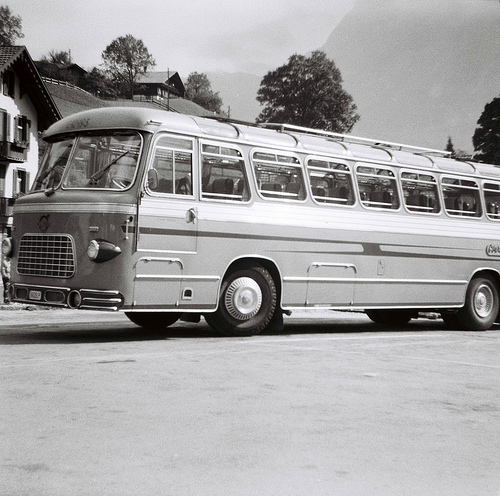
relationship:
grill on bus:
[17, 232, 77, 279] [2, 106, 499, 338]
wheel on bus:
[442, 274, 499, 330] [2, 106, 499, 338]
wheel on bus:
[204, 258, 279, 338] [2, 106, 499, 338]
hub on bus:
[224, 276, 263, 322] [2, 106, 499, 338]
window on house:
[1, 70, 15, 99] [1, 43, 65, 230]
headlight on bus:
[2, 238, 13, 258] [2, 106, 499, 338]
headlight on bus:
[85, 238, 99, 261] [2, 106, 499, 338]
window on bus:
[197, 138, 251, 203] [2, 106, 499, 338]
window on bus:
[250, 148, 308, 202] [2, 106, 499, 338]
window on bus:
[302, 155, 356, 209] [2, 106, 499, 338]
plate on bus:
[28, 289, 43, 303] [2, 106, 499, 338]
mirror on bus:
[146, 168, 159, 192] [2, 106, 499, 338]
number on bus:
[64, 117, 90, 130] [2, 106, 499, 338]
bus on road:
[2, 106, 499, 338] [3, 337, 499, 495]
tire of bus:
[204, 258, 279, 338] [2, 106, 499, 338]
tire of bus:
[442, 274, 499, 330] [2, 106, 499, 338]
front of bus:
[2, 108, 150, 308] [2, 106, 499, 338]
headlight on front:
[2, 238, 13, 258] [2, 108, 150, 308]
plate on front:
[28, 289, 43, 303] [2, 108, 150, 308]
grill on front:
[17, 232, 77, 279] [2, 108, 150, 308]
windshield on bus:
[31, 130, 144, 190] [2, 106, 499, 338]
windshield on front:
[31, 130, 144, 190] [2, 108, 150, 308]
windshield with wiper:
[31, 130, 144, 190] [89, 149, 132, 182]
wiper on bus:
[89, 149, 132, 182] [2, 106, 499, 338]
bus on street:
[2, 106, 499, 338] [3, 337, 499, 495]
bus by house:
[2, 106, 499, 338] [1, 43, 65, 230]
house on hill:
[100, 66, 186, 105] [47, 82, 171, 119]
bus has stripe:
[2, 106, 499, 338] [12, 191, 499, 242]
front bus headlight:
[2, 108, 150, 308] [2, 238, 13, 258]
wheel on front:
[442, 274, 499, 330] [2, 108, 150, 308]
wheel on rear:
[442, 274, 499, 330] [449, 156, 499, 310]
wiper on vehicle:
[89, 149, 132, 182] [2, 106, 499, 338]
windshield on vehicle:
[31, 130, 144, 190] [2, 106, 499, 338]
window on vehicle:
[197, 138, 251, 203] [2, 106, 499, 338]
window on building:
[1, 70, 15, 99] [1, 43, 65, 230]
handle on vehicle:
[186, 207, 197, 223] [2, 106, 499, 338]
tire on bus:
[125, 310, 182, 330] [2, 106, 499, 338]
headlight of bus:
[2, 238, 13, 258] [2, 106, 499, 338]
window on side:
[302, 155, 356, 209] [2, 106, 499, 338]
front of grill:
[2, 108, 150, 308] [17, 232, 77, 279]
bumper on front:
[3, 281, 125, 313] [2, 108, 150, 308]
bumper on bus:
[3, 281, 125, 313] [2, 106, 499, 338]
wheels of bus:
[123, 263, 499, 331] [2, 106, 499, 338]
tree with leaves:
[257, 49, 360, 134] [316, 64, 335, 88]